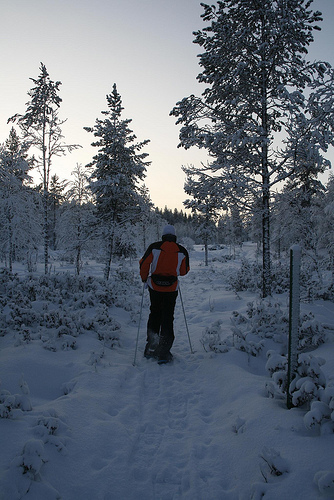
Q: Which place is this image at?
A: It is at the forest.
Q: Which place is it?
A: It is a forest.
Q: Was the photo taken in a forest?
A: Yes, it was taken in a forest.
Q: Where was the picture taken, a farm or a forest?
A: It was taken at a forest.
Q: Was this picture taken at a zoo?
A: No, the picture was taken in a forest.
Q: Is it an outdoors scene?
A: Yes, it is outdoors.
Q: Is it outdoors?
A: Yes, it is outdoors.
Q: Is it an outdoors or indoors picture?
A: It is outdoors.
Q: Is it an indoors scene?
A: No, it is outdoors.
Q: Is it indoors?
A: No, it is outdoors.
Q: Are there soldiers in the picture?
A: No, there are no soldiers.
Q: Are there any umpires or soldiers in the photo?
A: No, there are no soldiers or umpires.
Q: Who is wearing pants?
A: The skier is wearing pants.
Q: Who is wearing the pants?
A: The skier is wearing pants.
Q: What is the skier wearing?
A: The skier is wearing pants.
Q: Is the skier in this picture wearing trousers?
A: Yes, the skier is wearing trousers.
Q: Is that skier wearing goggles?
A: No, the skier is wearing trousers.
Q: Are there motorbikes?
A: No, there are no motorbikes.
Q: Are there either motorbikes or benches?
A: No, there are no motorbikes or benches.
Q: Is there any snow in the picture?
A: Yes, there is snow.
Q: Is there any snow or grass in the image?
A: Yes, there is snow.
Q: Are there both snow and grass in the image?
A: Yes, there are both snow and grass.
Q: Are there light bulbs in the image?
A: No, there are no light bulbs.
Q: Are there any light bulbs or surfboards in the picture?
A: No, there are no light bulbs or surfboards.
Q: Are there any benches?
A: No, there are no benches.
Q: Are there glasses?
A: No, there are no glasses.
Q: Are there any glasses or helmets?
A: No, there are no glasses or helmets.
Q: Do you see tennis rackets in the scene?
A: No, there are no tennis rackets.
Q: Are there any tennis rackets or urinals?
A: No, there are no tennis rackets or urinals.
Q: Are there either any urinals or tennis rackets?
A: No, there are no tennis rackets or urinals.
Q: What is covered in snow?
A: The brush is covered in snow.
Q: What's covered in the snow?
A: The brush is covered in snow.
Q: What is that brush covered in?
A: The brush is covered in snow.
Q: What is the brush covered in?
A: The brush is covered in snow.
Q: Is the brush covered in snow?
A: Yes, the brush is covered in snow.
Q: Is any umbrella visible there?
A: No, there are no umbrellas.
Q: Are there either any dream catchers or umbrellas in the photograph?
A: No, there are no umbrellas or dream catchers.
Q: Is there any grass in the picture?
A: Yes, there is grass.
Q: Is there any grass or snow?
A: Yes, there is grass.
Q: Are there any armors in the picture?
A: No, there are no armors.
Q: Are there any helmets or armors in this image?
A: No, there are no armors or helmets.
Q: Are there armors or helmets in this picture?
A: No, there are no armors or helmets.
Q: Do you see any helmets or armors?
A: No, there are no armors or helmets.